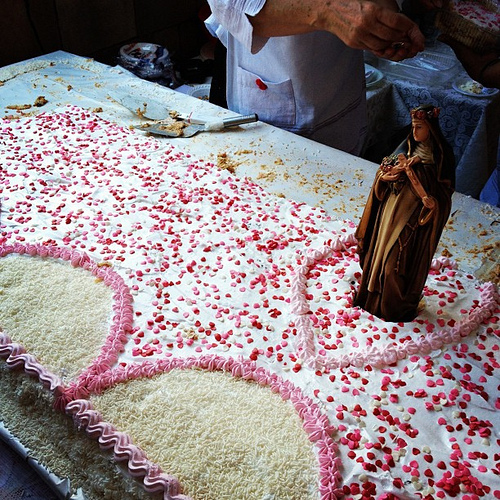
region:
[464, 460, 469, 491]
THE PETAL IS RED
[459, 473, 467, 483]
THE PETAL IS RED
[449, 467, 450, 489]
THE PETAL IS RED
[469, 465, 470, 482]
THE PETAL IS RED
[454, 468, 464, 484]
THE PETAL IS RED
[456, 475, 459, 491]
THE PETAL IS RED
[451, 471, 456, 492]
THE PETAL IS RED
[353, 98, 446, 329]
Holy statue on the cake.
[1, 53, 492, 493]
Pink small heart decorations on cake.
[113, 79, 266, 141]
Serving utensils serving cake.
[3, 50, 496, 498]
White table on which cake was sitting.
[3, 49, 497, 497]
Small red heart decorations on a cake.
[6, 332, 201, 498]
Scalloping with frosting on the cake.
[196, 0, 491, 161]
Person serving the cake.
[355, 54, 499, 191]
Lace tablecloth in the background.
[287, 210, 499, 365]
Frosting surrounding the statue.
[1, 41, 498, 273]
Crumbs left over from cake being cut.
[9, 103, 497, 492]
a large decorated cake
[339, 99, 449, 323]
a Madonna statuette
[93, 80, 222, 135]
a cake cutting knife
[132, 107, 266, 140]
a cake cutting knife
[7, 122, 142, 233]
pink sprinkles on white frosting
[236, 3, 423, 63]
a man's right hand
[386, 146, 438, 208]
statue of Jesus on cross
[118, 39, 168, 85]
a stack of paper plates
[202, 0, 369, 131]
a white chef's coat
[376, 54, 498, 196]
a blue tablecloth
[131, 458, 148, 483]
the icing is pink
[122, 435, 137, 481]
the icing is pink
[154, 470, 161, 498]
the icing is pink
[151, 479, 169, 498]
the icing is pink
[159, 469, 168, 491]
the icing is pink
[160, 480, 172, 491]
the icing is pink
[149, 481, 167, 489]
the icing is pink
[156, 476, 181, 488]
the icing is pink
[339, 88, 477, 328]
a religious statue holding a cross in robes on a cake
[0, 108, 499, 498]
a cake decorated with white and pink frosting and red and pink heart shaped sprinkles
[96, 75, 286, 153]
cake decorating tools that have been used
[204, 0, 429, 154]
hands and front of baker who made the cake wearing a white shirt and apron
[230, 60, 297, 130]
red button on the pocket of an apron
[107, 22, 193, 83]
blue and white ceramic bowl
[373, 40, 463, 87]
plastic disposable container sitting on a table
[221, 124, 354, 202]
cake crumbs on a white table cloth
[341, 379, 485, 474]
red, pink, and white heart shaped sprinkles on a cake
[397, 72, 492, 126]
table with a white lace table cloth and a plate with some food on it